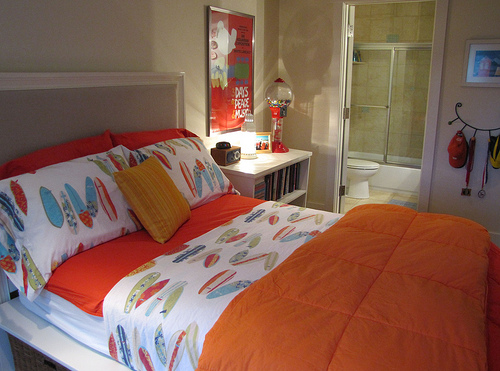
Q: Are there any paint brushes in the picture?
A: No, there are no paint brushes.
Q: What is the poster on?
A: The poster is on the wall.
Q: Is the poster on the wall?
A: Yes, the poster is on the wall.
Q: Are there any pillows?
A: Yes, there are pillows.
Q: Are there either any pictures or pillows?
A: Yes, there are pillows.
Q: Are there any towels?
A: No, there are no towels.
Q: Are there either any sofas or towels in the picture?
A: No, there are no towels or sofas.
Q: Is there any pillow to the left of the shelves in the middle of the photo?
A: Yes, there are pillows to the left of the shelves.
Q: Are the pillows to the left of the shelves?
A: Yes, the pillows are to the left of the shelves.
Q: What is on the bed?
A: The sheets are on the bed.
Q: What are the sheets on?
A: The sheets are on the bed.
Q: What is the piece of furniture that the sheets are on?
A: The piece of furniture is a bed.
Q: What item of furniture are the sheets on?
A: The sheets are on the bed.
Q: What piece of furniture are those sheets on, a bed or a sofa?
A: The sheets are on a bed.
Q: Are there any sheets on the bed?
A: Yes, there are sheets on the bed.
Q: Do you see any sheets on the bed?
A: Yes, there are sheets on the bed.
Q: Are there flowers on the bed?
A: No, there are sheets on the bed.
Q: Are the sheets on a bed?
A: Yes, the sheets are on a bed.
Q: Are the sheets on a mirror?
A: No, the sheets are on a bed.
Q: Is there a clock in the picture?
A: Yes, there is a clock.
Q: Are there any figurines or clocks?
A: Yes, there is a clock.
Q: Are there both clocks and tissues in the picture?
A: No, there is a clock but no tissues.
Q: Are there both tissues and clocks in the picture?
A: No, there is a clock but no tissues.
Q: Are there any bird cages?
A: No, there are no bird cages.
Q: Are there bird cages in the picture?
A: No, there are no bird cages.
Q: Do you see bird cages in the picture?
A: No, there are no bird cages.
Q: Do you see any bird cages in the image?
A: No, there are no bird cages.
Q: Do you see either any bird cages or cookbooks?
A: No, there are no bird cages or cookbooks.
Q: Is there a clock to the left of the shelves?
A: Yes, there is a clock to the left of the shelves.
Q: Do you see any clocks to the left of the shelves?
A: Yes, there is a clock to the left of the shelves.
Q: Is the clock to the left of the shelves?
A: Yes, the clock is to the left of the shelves.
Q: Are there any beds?
A: Yes, there is a bed.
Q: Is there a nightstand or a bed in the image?
A: Yes, there is a bed.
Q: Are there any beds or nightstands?
A: Yes, there is a bed.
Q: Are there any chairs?
A: No, there are no chairs.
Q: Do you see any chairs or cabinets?
A: No, there are no chairs or cabinets.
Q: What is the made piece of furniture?
A: The piece of furniture is a bed.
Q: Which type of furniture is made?
A: The furniture is a bed.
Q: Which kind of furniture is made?
A: The furniture is a bed.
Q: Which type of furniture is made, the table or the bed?
A: The bed is made.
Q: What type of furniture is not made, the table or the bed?
A: The table is not made.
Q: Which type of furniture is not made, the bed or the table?
A: The table is not made.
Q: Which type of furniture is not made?
A: The furniture is a table.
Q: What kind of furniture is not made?
A: The furniture is a table.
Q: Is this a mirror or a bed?
A: This is a bed.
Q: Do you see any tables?
A: Yes, there is a table.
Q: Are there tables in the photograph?
A: Yes, there is a table.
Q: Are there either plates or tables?
A: Yes, there is a table.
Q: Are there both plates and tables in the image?
A: No, there is a table but no plates.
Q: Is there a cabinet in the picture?
A: No, there are no cabinets.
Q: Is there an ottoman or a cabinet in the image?
A: No, there are no cabinets or ottomen.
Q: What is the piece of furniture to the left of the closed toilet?
A: The piece of furniture is a table.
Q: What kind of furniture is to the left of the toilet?
A: The piece of furniture is a table.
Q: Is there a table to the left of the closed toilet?
A: Yes, there is a table to the left of the toilet.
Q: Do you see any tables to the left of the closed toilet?
A: Yes, there is a table to the left of the toilet.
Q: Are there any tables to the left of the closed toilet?
A: Yes, there is a table to the left of the toilet.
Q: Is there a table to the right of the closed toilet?
A: No, the table is to the left of the toilet.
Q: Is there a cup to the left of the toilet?
A: No, there is a table to the left of the toilet.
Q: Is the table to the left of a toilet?
A: Yes, the table is to the left of a toilet.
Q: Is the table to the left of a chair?
A: No, the table is to the left of a toilet.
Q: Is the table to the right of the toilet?
A: No, the table is to the left of the toilet.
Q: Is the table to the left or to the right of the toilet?
A: The table is to the left of the toilet.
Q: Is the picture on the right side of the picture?
A: Yes, the picture is on the right of the image.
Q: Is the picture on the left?
A: No, the picture is on the right of the image.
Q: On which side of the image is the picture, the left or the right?
A: The picture is on the right of the image.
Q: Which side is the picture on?
A: The picture is on the right of the image.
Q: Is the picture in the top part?
A: Yes, the picture is in the top of the image.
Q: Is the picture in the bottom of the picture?
A: No, the picture is in the top of the image.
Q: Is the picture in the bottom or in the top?
A: The picture is in the top of the image.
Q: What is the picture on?
A: The picture is on the wall.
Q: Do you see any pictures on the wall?
A: Yes, there is a picture on the wall.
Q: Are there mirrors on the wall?
A: No, there is a picture on the wall.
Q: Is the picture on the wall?
A: Yes, the picture is on the wall.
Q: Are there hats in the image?
A: Yes, there is a hat.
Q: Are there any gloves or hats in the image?
A: Yes, there is a hat.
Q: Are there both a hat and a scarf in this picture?
A: No, there is a hat but no scarves.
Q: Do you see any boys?
A: No, there are no boys.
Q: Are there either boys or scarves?
A: No, there are no boys or scarves.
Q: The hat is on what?
A: The hat is on the wall.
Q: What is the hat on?
A: The hat is on the wall.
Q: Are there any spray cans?
A: No, there are no spray cans.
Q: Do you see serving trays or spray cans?
A: No, there are no spray cans or serving trays.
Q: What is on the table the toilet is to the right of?
A: The machine is on the table.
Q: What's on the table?
A: The machine is on the table.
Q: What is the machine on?
A: The machine is on the table.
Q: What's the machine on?
A: The machine is on the table.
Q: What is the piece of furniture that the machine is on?
A: The piece of furniture is a table.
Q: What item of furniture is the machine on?
A: The machine is on the table.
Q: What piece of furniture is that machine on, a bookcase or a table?
A: The machine is on a table.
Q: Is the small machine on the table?
A: Yes, the machine is on the table.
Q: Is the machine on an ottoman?
A: No, the machine is on the table.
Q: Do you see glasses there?
A: No, there are no glasses.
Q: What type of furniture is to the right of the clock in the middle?
A: The pieces of furniture are shelves.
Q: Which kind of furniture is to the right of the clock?
A: The pieces of furniture are shelves.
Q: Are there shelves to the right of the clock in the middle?
A: Yes, there are shelves to the right of the clock.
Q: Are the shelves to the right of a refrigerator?
A: No, the shelves are to the right of the clock.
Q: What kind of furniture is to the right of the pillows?
A: The pieces of furniture are shelves.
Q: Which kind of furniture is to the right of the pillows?
A: The pieces of furniture are shelves.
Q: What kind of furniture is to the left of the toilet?
A: The pieces of furniture are shelves.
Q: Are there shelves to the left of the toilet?
A: Yes, there are shelves to the left of the toilet.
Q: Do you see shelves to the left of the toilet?
A: Yes, there are shelves to the left of the toilet.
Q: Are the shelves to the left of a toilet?
A: Yes, the shelves are to the left of a toilet.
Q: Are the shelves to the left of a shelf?
A: No, the shelves are to the left of a toilet.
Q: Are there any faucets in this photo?
A: No, there are no faucets.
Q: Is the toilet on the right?
A: Yes, the toilet is on the right of the image.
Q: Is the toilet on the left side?
A: No, the toilet is on the right of the image.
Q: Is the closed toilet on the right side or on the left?
A: The toilet is on the right of the image.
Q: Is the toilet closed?
A: Yes, the toilet is closed.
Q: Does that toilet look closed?
A: Yes, the toilet is closed.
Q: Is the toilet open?
A: No, the toilet is closed.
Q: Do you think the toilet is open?
A: No, the toilet is closed.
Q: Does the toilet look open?
A: No, the toilet is closed.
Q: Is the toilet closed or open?
A: The toilet is closed.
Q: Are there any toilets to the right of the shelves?
A: Yes, there is a toilet to the right of the shelves.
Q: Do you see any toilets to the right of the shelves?
A: Yes, there is a toilet to the right of the shelves.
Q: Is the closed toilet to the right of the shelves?
A: Yes, the toilet is to the right of the shelves.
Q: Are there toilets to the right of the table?
A: Yes, there is a toilet to the right of the table.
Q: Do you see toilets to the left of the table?
A: No, the toilet is to the right of the table.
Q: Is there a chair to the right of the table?
A: No, there is a toilet to the right of the table.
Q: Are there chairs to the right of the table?
A: No, there is a toilet to the right of the table.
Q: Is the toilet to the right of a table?
A: Yes, the toilet is to the right of a table.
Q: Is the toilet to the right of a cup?
A: No, the toilet is to the right of a table.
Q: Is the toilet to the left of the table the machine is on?
A: No, the toilet is to the right of the table.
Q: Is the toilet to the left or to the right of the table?
A: The toilet is to the right of the table.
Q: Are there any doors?
A: Yes, there is a door.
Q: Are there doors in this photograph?
A: Yes, there is a door.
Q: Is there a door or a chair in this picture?
A: Yes, there is a door.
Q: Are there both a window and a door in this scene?
A: No, there is a door but no windows.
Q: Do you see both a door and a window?
A: No, there is a door but no windows.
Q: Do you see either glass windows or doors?
A: Yes, there is a glass door.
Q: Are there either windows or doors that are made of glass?
A: Yes, the door is made of glass.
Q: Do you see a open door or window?
A: Yes, there is an open door.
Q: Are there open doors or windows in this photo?
A: Yes, there is an open door.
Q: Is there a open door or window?
A: Yes, there is an open door.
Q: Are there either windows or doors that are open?
A: Yes, the door is open.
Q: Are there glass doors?
A: Yes, there is a door that is made of glass.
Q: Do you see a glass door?
A: Yes, there is a door that is made of glass.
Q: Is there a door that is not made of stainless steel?
A: Yes, there is a door that is made of glass.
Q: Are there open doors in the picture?
A: Yes, there is an open door.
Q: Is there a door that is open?
A: Yes, there is a door that is open.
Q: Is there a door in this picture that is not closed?
A: Yes, there is a open door.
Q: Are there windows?
A: No, there are no windows.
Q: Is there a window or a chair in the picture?
A: No, there are no windows or chairs.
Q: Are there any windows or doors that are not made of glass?
A: No, there is a door but it is made of glass.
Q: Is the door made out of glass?
A: Yes, the door is made of glass.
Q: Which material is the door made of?
A: The door is made of glass.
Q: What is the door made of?
A: The door is made of glass.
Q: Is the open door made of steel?
A: No, the door is made of glass.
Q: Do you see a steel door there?
A: No, there is a door but it is made of glass.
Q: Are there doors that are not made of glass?
A: No, there is a door but it is made of glass.